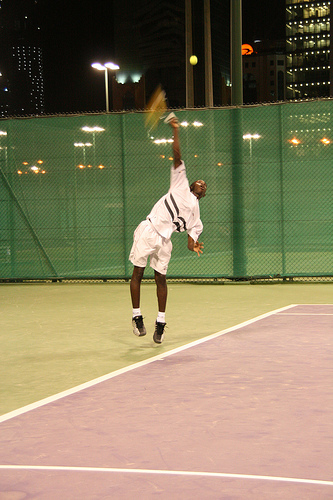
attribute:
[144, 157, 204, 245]
shirt — white, black, short sleeved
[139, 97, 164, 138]
racket — up, high, blurry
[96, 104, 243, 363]
player — has white socks, black, tall, skinny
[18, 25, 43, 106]
building — tall, dark, lighted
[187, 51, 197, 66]
ball — high, small, round, yellow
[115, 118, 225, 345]
tennis player — black, tall, skinny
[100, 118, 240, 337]
man —  black, tall, skinny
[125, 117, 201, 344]
man — has black shoes, black, has white socks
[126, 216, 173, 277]
shorts — white, loose, medium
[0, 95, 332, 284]
fence — tall, green, wide, wiry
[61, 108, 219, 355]
man — skinny, black, has white shirt, has black shoes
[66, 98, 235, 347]
man — tall, black, skinny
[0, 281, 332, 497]
court — wide, pink, yellow, white, flat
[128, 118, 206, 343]
man — black, has white shirt, has white shorts, tall, skinny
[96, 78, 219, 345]
man — black, tall, skinny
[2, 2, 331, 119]
sky — dark,  black, lighted